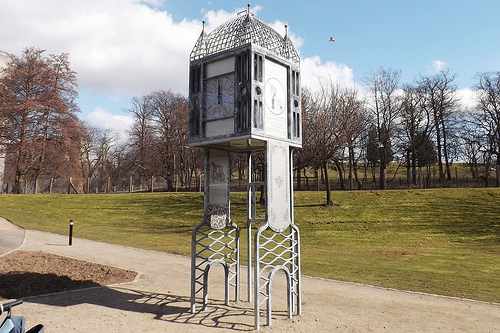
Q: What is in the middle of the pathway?
A: A clock.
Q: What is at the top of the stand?
A: Small clock tower.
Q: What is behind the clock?
A: Grass.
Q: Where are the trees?
A: In the field.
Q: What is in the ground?
A: Shadow.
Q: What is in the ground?
A: Trees.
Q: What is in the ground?
A: Tower.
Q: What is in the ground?
A: Trees.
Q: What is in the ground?
A: Fence.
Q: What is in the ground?
A: Clock.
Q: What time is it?
A: Afternoon.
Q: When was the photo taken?
A: During the daytime.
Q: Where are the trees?
A: In the distance.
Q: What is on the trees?
A: Branches.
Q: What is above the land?
A: Sky.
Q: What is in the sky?
A: Clouds.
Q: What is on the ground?
A: Grass.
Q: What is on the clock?
A: Hands.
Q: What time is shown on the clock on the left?
A: Noon.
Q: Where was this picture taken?
A: A Park.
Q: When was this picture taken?
A: Daytime.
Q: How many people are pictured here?
A: Zero.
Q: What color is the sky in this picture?
A: Blue.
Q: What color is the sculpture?
A: White.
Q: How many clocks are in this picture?
A: Two.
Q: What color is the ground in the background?
A: Green.